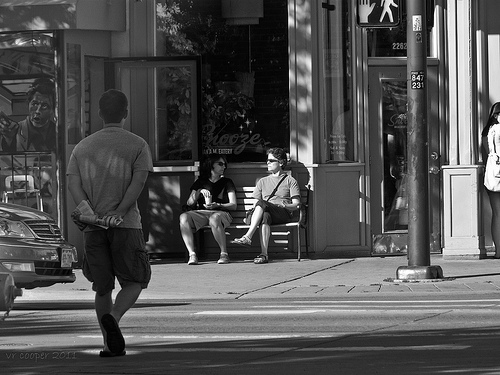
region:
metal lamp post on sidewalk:
[400, 7, 437, 294]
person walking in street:
[62, 87, 154, 363]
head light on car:
[0, 217, 37, 240]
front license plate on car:
[57, 241, 78, 274]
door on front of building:
[364, 62, 444, 252]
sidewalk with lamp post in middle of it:
[14, 253, 497, 298]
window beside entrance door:
[320, 1, 357, 161]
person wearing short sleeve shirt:
[67, 127, 149, 234]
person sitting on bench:
[243, 147, 303, 259]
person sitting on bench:
[181, 157, 233, 262]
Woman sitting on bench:
[177, 150, 241, 272]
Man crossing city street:
[59, 83, 155, 366]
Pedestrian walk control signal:
[343, 1, 402, 28]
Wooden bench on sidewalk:
[184, 180, 315, 261]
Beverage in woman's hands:
[197, 188, 214, 208]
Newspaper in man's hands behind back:
[71, 197, 123, 234]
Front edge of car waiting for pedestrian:
[1, 196, 82, 287]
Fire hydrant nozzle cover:
[2, 267, 24, 323]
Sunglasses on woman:
[261, 157, 281, 165]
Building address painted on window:
[387, 38, 406, 51]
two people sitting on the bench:
[161, 146, 333, 263]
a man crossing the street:
[61, 65, 214, 347]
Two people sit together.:
[177, 148, 302, 265]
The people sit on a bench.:
[177, 148, 309, 265]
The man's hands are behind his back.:
[70, 207, 125, 233]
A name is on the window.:
[202, 120, 262, 155]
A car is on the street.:
[0, 205, 78, 270]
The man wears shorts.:
[79, 228, 150, 290]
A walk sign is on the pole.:
[355, 0, 400, 27]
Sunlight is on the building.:
[291, 12, 312, 134]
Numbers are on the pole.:
[410, 74, 425, 88]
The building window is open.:
[153, 57, 199, 167]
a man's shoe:
[97, 310, 130, 356]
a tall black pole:
[402, 0, 440, 267]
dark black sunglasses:
[262, 155, 282, 164]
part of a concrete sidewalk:
[40, 242, 495, 292]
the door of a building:
[370, 70, 442, 250]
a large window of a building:
[150, 1, 295, 163]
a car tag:
[56, 241, 76, 262]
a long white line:
[195, 305, 320, 316]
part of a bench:
[241, 185, 301, 247]